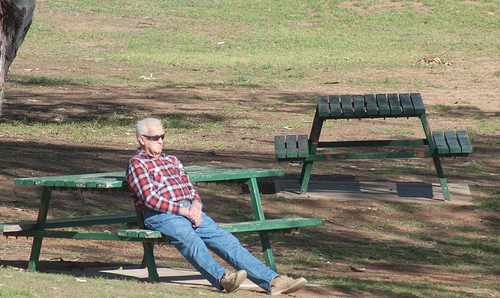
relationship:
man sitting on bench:
[127, 117, 309, 295] [1, 134, 333, 292]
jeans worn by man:
[139, 201, 292, 296] [127, 117, 309, 295]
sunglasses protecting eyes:
[138, 131, 168, 141] [147, 135, 159, 138]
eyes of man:
[147, 135, 159, 138] [127, 117, 309, 295]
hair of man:
[134, 115, 163, 138] [127, 117, 309, 295]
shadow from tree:
[0, 89, 498, 295] [0, 0, 37, 88]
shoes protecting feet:
[225, 266, 305, 296] [220, 269, 307, 295]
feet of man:
[220, 269, 307, 295] [127, 117, 309, 295]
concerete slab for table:
[272, 172, 477, 207] [271, 91, 473, 203]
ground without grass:
[306, 210, 496, 282] [413, 202, 482, 222]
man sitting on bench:
[127, 117, 309, 295] [2, 165, 324, 279]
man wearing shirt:
[127, 117, 309, 295] [127, 146, 200, 214]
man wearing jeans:
[127, 117, 309, 295] [136, 198, 278, 291]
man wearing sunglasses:
[127, 117, 309, 295] [140, 135, 164, 142]